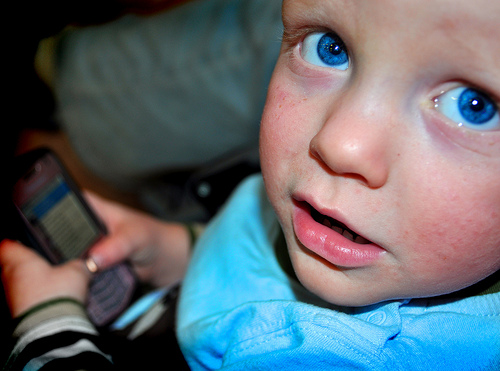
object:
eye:
[297, 29, 352, 71]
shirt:
[170, 170, 500, 371]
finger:
[89, 226, 137, 272]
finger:
[62, 258, 95, 281]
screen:
[3, 147, 137, 325]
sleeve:
[180, 218, 209, 260]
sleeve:
[0, 291, 121, 371]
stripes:
[180, 215, 209, 247]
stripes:
[7, 351, 114, 371]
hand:
[81, 188, 181, 288]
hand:
[0, 238, 89, 317]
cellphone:
[3, 143, 138, 331]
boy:
[2, 0, 499, 370]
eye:
[429, 83, 499, 133]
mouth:
[286, 188, 387, 269]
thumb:
[86, 224, 137, 276]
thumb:
[58, 254, 93, 280]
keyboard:
[85, 263, 137, 324]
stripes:
[128, 298, 163, 339]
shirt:
[0, 166, 196, 371]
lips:
[277, 201, 394, 273]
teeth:
[300, 209, 370, 248]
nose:
[302, 80, 390, 196]